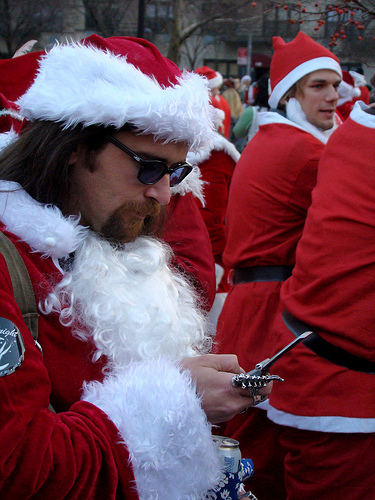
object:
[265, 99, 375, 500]
person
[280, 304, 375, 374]
belt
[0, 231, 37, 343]
strap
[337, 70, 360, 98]
santa hat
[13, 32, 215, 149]
hat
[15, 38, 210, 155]
fur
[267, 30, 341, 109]
santa hat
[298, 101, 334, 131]
beard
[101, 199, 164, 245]
goatee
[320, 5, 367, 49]
limbs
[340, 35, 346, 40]
red bulbs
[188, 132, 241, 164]
cuff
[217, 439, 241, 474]
can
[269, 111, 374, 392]
body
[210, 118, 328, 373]
body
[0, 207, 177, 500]
body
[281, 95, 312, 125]
ground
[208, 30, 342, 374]
guy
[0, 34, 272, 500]
guy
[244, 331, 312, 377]
cell phone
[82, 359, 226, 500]
cuff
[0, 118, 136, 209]
hair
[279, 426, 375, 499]
pants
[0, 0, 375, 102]
building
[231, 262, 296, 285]
black belt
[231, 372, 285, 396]
ring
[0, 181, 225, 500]
jacket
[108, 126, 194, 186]
sunglasses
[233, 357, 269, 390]
bulbs